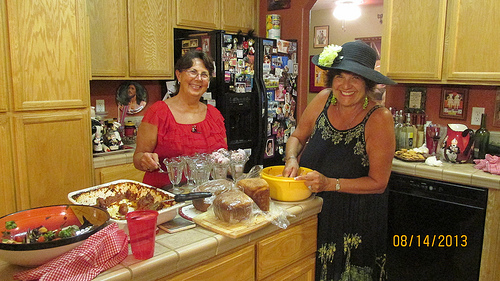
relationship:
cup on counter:
[119, 206, 159, 263] [10, 171, 331, 278]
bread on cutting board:
[212, 184, 262, 227] [196, 203, 276, 243]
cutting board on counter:
[192, 209, 279, 241] [6, 189, 322, 278]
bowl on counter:
[258, 147, 321, 216] [6, 189, 322, 278]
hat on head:
[312, 42, 398, 84] [320, 56, 387, 118]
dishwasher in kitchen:
[381, 173, 485, 281] [2, 2, 496, 280]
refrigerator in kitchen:
[171, 21, 303, 176] [2, 2, 496, 280]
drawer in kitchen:
[252, 214, 321, 277] [2, 2, 496, 280]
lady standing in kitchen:
[283, 40, 398, 281] [2, 2, 496, 280]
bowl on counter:
[1, 204, 110, 266] [10, 171, 331, 278]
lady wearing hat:
[283, 40, 398, 281] [312, 31, 395, 83]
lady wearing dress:
[283, 40, 398, 281] [294, 85, 404, 275]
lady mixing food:
[283, 40, 398, 281] [269, 163, 309, 180]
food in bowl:
[269, 163, 309, 180] [254, 160, 322, 202]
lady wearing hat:
[283, 40, 398, 281] [307, 29, 402, 90]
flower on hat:
[316, 36, 350, 78] [302, 36, 388, 96]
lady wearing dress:
[283, 40, 398, 281] [296, 83, 384, 279]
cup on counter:
[126, 211, 159, 259] [6, 189, 322, 278]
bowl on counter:
[258, 165, 316, 202] [6, 189, 322, 278]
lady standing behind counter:
[132, 51, 226, 189] [6, 189, 322, 278]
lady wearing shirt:
[132, 51, 226, 189] [135, 100, 227, 190]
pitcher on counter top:
[441, 124, 476, 164] [391, 145, 497, 187]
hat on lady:
[311, 35, 407, 100] [288, 33, 448, 250]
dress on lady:
[287, 114, 409, 274] [271, 41, 414, 258]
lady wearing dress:
[283, 40, 398, 281] [297, 96, 397, 274]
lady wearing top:
[132, 51, 233, 207] [142, 100, 218, 180]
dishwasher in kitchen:
[381, 171, 482, 276] [2, 2, 496, 280]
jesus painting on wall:
[115, 82, 148, 114] [90, 0, 300, 178]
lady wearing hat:
[292, 33, 408, 273] [312, 34, 388, 83]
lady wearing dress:
[283, 40, 398, 281] [301, 91, 402, 280]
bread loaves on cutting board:
[206, 178, 282, 225] [179, 202, 306, 242]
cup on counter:
[126, 211, 159, 259] [10, 171, 331, 278]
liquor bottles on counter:
[382, 104, 434, 165] [395, 144, 498, 196]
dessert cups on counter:
[162, 145, 258, 201] [6, 189, 322, 278]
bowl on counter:
[258, 165, 316, 202] [10, 184, 328, 280]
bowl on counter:
[258, 165, 316, 202] [0, 184, 324, 280]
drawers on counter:
[175, 214, 329, 279] [10, 171, 331, 278]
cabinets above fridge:
[172, 7, 266, 41] [173, 27, 298, 177]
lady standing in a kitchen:
[132, 51, 226, 189] [2, 2, 496, 280]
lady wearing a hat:
[283, 40, 398, 281] [312, 42, 398, 84]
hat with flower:
[312, 42, 398, 84] [317, 36, 342, 65]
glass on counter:
[128, 205, 158, 257] [10, 171, 331, 278]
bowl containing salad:
[6, 193, 115, 280] [1, 209, 108, 252]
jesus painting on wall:
[112, 85, 150, 130] [90, 0, 300, 178]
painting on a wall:
[435, 89, 469, 119] [270, 5, 497, 155]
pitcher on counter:
[441, 121, 476, 164] [392, 142, 499, 188]